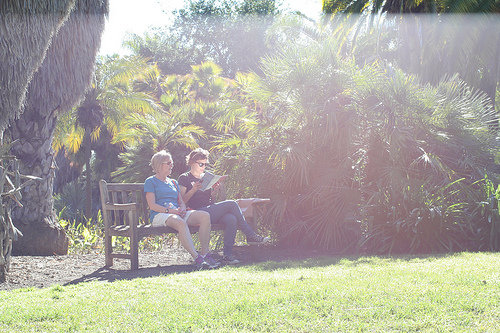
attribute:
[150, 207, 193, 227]
pants — white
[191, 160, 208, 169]
glasses — short, black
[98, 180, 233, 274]
bench — brown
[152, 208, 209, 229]
shorts — white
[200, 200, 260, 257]
jeans — blue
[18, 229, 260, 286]
shadow — bench, black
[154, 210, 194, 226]
shorts — white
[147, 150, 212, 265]
woman — blond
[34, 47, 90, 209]
bark — layered, rough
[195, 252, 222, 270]
sneakers — purple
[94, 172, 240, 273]
bench — wooden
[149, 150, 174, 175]
hair — blond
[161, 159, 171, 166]
glasses — framed, white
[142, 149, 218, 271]
woman — blonde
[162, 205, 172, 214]
watch — black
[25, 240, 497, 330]
grass — green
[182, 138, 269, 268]
woman — reading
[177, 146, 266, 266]
woman — seated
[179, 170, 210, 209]
shirt — black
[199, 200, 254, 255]
pants — blue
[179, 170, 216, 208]
shirt — black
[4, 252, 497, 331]
grass — green, bright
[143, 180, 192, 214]
shirt — blue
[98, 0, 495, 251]
trees — leafy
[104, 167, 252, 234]
bench — wooden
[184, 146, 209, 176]
hair — brown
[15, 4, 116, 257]
tree — furry, large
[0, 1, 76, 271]
tree — furry, large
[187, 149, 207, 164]
hair — brown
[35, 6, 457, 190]
sunshine — bright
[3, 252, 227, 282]
path — gravel, dirt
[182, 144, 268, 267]
person — talking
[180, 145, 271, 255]
person — talking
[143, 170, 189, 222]
shirt — blue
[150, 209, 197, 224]
shorts — white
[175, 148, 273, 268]
woman — seated